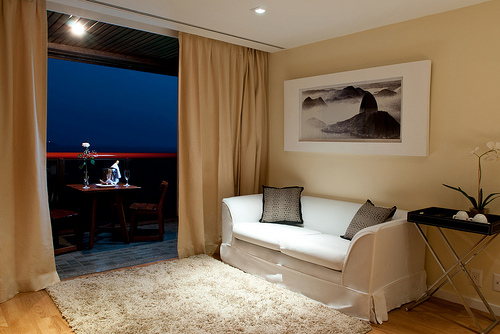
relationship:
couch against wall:
[216, 185, 430, 327] [265, 2, 496, 316]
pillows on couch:
[255, 178, 396, 243] [222, 187, 426, 317]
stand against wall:
[406, 204, 498, 331] [265, 2, 496, 316]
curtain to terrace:
[1, 0, 59, 305] [45, 34, 180, 281]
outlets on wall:
[463, 262, 498, 300] [265, 2, 496, 316]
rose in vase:
[81, 139, 93, 151] [80, 163, 92, 190]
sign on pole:
[38, 104, 163, 191] [44, 105, 171, 265]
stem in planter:
[474, 152, 484, 207] [461, 206, 490, 221]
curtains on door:
[176, 31, 270, 258] [38, 12, 238, 272]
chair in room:
[131, 175, 169, 241] [46, 7, 181, 279]